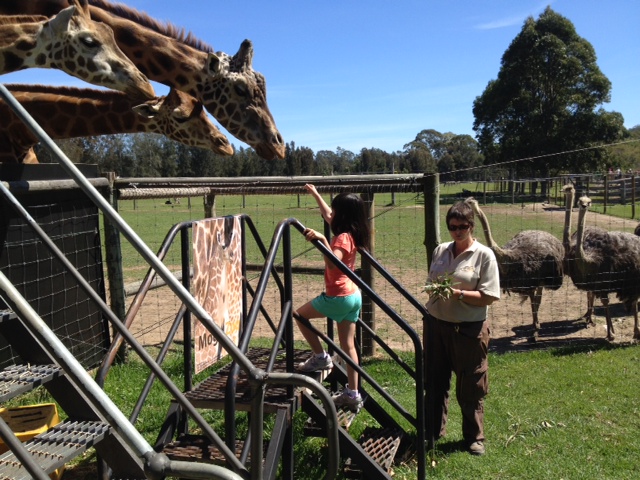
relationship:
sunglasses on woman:
[441, 217, 477, 231] [411, 201, 497, 455]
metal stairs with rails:
[0, 342, 428, 478] [111, 220, 426, 343]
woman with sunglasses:
[411, 201, 497, 455] [446, 218, 474, 234]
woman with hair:
[411, 201, 497, 455] [445, 196, 478, 233]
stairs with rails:
[190, 340, 406, 472] [326, 214, 432, 457]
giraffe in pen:
[7, 81, 244, 159] [20, 166, 638, 322]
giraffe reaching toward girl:
[7, 81, 244, 159] [295, 183, 368, 403]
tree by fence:
[469, 5, 633, 202] [116, 174, 639, 348]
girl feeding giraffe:
[295, 183, 368, 403] [1, 3, 287, 161]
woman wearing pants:
[411, 201, 497, 455] [418, 312, 492, 440]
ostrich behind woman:
[450, 192, 633, 338] [429, 195, 502, 461]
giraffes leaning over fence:
[3, 4, 305, 249] [112, 166, 620, 353]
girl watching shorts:
[295, 183, 368, 403] [306, 283, 360, 325]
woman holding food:
[421, 201, 500, 455] [413, 266, 465, 302]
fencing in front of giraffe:
[0, 176, 216, 365] [1, 2, 151, 101]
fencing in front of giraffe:
[0, 176, 216, 365] [1, 3, 287, 161]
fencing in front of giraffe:
[0, 176, 216, 365] [2, 82, 232, 161]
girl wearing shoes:
[288, 185, 378, 406] [405, 408, 515, 460]